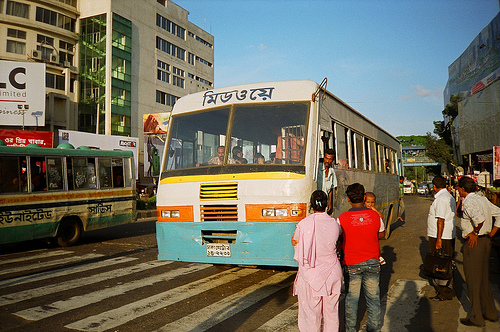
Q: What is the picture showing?
A: It is showing a street.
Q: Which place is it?
A: It is a street.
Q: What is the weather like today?
A: It is clear.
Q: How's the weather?
A: It is clear.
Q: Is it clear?
A: Yes, it is clear.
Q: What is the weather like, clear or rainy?
A: It is clear.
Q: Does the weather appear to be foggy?
A: No, it is clear.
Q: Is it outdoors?
A: Yes, it is outdoors.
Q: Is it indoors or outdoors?
A: It is outdoors.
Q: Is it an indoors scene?
A: No, it is outdoors.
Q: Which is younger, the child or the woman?
A: The child is younger than the woman.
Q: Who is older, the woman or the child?
A: The woman is older than the child.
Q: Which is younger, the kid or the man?
A: The kid is younger than the man.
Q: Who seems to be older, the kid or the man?
A: The man is older than the kid.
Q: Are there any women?
A: Yes, there is a woman.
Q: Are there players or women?
A: Yes, there is a woman.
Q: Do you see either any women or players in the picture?
A: Yes, there is a woman.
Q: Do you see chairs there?
A: No, there are no chairs.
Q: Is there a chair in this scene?
A: No, there are no chairs.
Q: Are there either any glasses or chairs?
A: No, there are no chairs or glasses.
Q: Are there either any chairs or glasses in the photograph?
A: No, there are no chairs or glasses.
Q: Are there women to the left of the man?
A: Yes, there is a woman to the left of the man.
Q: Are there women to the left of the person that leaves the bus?
A: Yes, there is a woman to the left of the man.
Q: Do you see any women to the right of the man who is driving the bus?
A: No, the woman is to the left of the man.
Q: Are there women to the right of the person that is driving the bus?
A: No, the woman is to the left of the man.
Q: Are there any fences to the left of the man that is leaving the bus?
A: No, there is a woman to the left of the man.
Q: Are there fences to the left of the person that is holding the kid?
A: No, there is a woman to the left of the man.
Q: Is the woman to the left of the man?
A: Yes, the woman is to the left of the man.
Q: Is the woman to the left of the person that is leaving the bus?
A: Yes, the woman is to the left of the man.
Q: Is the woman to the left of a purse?
A: No, the woman is to the left of the man.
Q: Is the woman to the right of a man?
A: No, the woman is to the left of a man.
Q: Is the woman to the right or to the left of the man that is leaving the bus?
A: The woman is to the left of the man.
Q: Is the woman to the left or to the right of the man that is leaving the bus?
A: The woman is to the left of the man.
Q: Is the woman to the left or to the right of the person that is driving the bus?
A: The woman is to the left of the man.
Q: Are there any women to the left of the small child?
A: Yes, there is a woman to the left of the child.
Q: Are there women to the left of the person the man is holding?
A: Yes, there is a woman to the left of the child.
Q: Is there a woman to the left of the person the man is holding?
A: Yes, there is a woman to the left of the child.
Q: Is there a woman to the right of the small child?
A: No, the woman is to the left of the kid.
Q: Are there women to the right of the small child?
A: No, the woman is to the left of the kid.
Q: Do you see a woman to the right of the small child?
A: No, the woman is to the left of the kid.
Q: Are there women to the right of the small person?
A: No, the woman is to the left of the kid.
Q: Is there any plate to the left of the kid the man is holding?
A: No, there is a woman to the left of the child.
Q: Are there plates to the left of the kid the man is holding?
A: No, there is a woman to the left of the child.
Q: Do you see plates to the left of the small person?
A: No, there is a woman to the left of the child.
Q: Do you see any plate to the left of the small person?
A: No, there is a woman to the left of the child.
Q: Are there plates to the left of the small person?
A: No, there is a woman to the left of the child.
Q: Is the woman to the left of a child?
A: Yes, the woman is to the left of a child.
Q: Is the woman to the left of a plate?
A: No, the woman is to the left of a child.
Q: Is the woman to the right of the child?
A: No, the woman is to the left of the child.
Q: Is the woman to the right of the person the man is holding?
A: No, the woman is to the left of the child.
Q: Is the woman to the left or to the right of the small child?
A: The woman is to the left of the kid.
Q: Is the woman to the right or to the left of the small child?
A: The woman is to the left of the kid.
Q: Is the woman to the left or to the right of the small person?
A: The woman is to the left of the kid.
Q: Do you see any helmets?
A: No, there are no helmets.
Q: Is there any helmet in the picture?
A: No, there are no helmets.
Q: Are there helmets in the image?
A: No, there are no helmets.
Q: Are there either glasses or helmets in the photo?
A: No, there are no helmets or glasses.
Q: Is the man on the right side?
A: Yes, the man is on the right of the image.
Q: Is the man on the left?
A: No, the man is on the right of the image.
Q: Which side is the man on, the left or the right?
A: The man is on the right of the image.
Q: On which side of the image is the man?
A: The man is on the right of the image.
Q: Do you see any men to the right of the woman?
A: Yes, there is a man to the right of the woman.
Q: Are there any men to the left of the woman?
A: No, the man is to the right of the woman.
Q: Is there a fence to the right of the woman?
A: No, there is a man to the right of the woman.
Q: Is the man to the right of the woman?
A: Yes, the man is to the right of the woman.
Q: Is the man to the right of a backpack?
A: No, the man is to the right of the woman.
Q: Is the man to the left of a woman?
A: No, the man is to the right of a woman.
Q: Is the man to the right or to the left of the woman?
A: The man is to the right of the woman.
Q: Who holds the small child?
A: The man holds the kid.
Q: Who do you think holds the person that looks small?
A: The man holds the kid.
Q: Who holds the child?
A: The man holds the kid.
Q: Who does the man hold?
A: The man holds the child.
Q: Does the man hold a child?
A: Yes, the man holds a child.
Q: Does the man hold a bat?
A: No, the man holds a child.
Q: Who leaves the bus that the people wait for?
A: The man leaves the bus.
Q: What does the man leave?
A: The man leaves the bus.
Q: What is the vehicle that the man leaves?
A: The vehicle is a bus.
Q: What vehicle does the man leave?
A: The man leaves the bus.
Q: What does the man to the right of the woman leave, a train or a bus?
A: The man leaves a bus.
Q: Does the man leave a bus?
A: Yes, the man leaves a bus.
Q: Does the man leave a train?
A: No, the man leaves a bus.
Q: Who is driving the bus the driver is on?
A: The man is driving the bus.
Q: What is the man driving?
A: The man is driving the bus.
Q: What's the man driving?
A: The man is driving the bus.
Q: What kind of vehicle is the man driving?
A: The man is driving the bus.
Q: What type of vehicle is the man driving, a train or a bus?
A: The man is driving a bus.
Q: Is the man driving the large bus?
A: Yes, the man is driving the bus.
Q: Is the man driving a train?
A: No, the man is driving the bus.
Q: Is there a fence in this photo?
A: No, there are no fences.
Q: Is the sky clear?
A: Yes, the sky is clear.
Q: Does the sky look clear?
A: Yes, the sky is clear.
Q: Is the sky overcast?
A: No, the sky is clear.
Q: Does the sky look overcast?
A: No, the sky is clear.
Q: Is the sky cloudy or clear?
A: The sky is clear.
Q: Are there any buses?
A: Yes, there is a bus.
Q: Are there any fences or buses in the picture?
A: Yes, there is a bus.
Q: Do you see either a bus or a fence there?
A: Yes, there is a bus.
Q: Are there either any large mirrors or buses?
A: Yes, there is a large bus.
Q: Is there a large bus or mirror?
A: Yes, there is a large bus.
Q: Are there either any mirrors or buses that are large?
A: Yes, the bus is large.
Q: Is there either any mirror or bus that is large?
A: Yes, the bus is large.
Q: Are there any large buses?
A: Yes, there is a large bus.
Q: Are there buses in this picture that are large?
A: Yes, there is a bus that is large.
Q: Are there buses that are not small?
A: Yes, there is a large bus.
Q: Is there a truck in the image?
A: No, there are no trucks.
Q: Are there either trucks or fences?
A: No, there are no trucks or fences.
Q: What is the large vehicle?
A: The vehicle is a bus.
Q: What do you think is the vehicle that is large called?
A: The vehicle is a bus.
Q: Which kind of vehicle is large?
A: The vehicle is a bus.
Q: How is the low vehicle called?
A: The vehicle is a bus.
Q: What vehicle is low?
A: The vehicle is a bus.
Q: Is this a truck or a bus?
A: This is a bus.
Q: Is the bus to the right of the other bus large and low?
A: Yes, the bus is large and low.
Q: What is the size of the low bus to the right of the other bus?
A: The bus is large.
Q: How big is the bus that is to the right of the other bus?
A: The bus is large.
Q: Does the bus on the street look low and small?
A: No, the bus is low but large.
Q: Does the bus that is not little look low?
A: Yes, the bus is low.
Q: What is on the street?
A: The bus is on the street.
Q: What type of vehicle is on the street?
A: The vehicle is a bus.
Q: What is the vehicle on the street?
A: The vehicle is a bus.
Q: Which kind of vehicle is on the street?
A: The vehicle is a bus.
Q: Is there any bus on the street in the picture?
A: Yes, there is a bus on the street.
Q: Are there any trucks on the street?
A: No, there is a bus on the street.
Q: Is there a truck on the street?
A: No, there is a bus on the street.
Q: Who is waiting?
A: The people are waiting.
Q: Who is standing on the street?
A: The people are standing on the street.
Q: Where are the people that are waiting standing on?
A: The people are standing on the street.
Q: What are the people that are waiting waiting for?
A: The people are waiting for the bus.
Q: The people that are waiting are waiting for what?
A: The people are waiting for the bus.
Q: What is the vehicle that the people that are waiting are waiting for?
A: The vehicle is a bus.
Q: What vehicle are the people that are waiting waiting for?
A: The people are waiting for the bus.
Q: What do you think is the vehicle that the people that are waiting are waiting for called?
A: The vehicle is a bus.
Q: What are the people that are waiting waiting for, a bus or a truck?
A: The people are waiting for a bus.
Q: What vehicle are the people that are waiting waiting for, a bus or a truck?
A: The people are waiting for a bus.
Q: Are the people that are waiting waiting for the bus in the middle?
A: Yes, the people are waiting for the bus.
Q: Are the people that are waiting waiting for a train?
A: No, the people are waiting for the bus.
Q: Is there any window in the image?
A: Yes, there is a window.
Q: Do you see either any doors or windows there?
A: Yes, there is a window.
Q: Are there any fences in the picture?
A: No, there are no fences.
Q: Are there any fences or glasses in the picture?
A: No, there are no fences or glasses.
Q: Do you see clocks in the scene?
A: No, there are no clocks.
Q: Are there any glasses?
A: No, there are no glasses.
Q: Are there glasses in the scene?
A: No, there are no glasses.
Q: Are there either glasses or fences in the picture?
A: No, there are no glasses or fences.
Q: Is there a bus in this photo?
A: Yes, there is a bus.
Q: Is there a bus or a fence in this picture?
A: Yes, there is a bus.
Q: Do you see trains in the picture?
A: No, there are no trains.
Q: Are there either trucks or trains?
A: No, there are no trains or trucks.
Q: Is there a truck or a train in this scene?
A: No, there are no trains or trucks.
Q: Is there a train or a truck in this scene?
A: No, there are no trains or trucks.